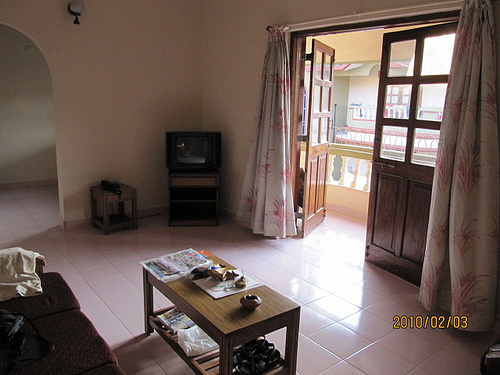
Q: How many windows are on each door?
A: Six.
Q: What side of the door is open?
A: The left.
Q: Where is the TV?
A: In the corner.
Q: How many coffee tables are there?
A: One.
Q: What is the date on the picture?
A: 2010/02/03.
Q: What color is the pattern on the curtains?
A: Pink.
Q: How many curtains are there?
A: Two.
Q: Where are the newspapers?
A: On the coffee table.